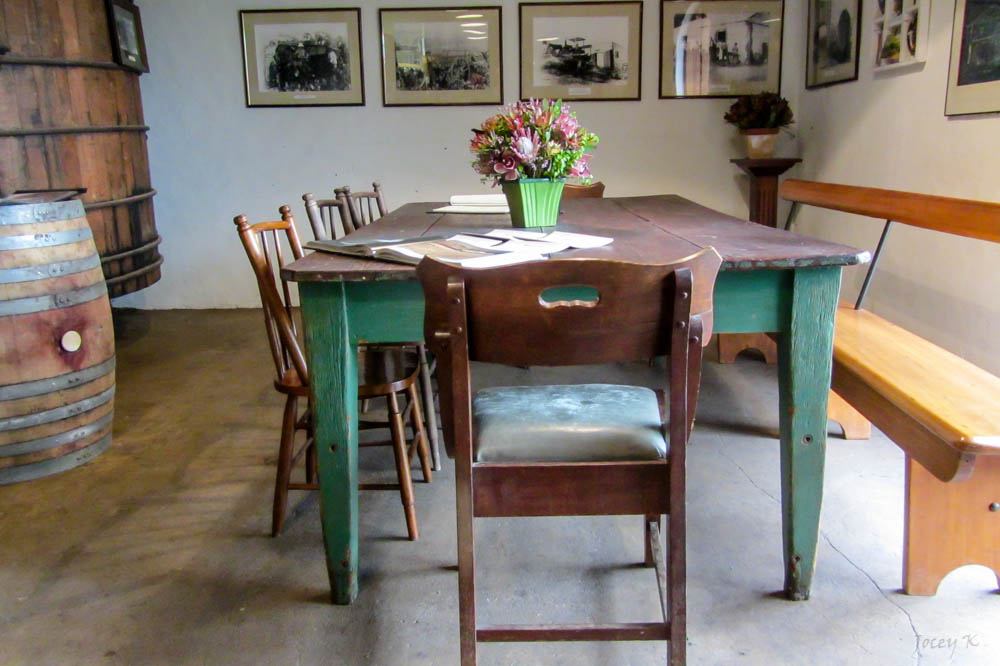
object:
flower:
[551, 114, 580, 137]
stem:
[558, 134, 563, 141]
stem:
[495, 127, 498, 132]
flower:
[482, 114, 499, 134]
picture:
[235, 5, 366, 112]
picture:
[375, 5, 504, 108]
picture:
[802, 1, 864, 90]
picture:
[869, 1, 921, 74]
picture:
[938, 0, 996, 123]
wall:
[788, 3, 1000, 370]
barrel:
[0, 185, 117, 487]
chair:
[411, 246, 723, 666]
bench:
[769, 175, 998, 597]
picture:
[651, 0, 782, 100]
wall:
[106, 1, 806, 306]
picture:
[517, 7, 639, 108]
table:
[277, 193, 874, 605]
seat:
[829, 298, 997, 601]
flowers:
[458, 92, 604, 188]